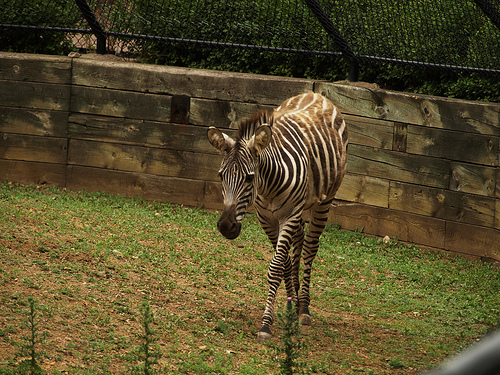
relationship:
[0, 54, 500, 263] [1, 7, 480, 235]
wall on side of a building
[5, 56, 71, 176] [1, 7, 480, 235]
wall on side of a building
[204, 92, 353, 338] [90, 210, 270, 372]
zebra standing in grass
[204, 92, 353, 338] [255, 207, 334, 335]
zebra has legs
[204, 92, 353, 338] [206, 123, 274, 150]
zebra has ears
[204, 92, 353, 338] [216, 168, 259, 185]
zebra has eyes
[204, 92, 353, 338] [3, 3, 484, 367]
zebra standing in an enclosure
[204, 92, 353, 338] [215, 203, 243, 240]
zebra has a snout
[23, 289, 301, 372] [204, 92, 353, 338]
trees in front of zebra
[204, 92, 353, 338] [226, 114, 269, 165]
zebra has a mane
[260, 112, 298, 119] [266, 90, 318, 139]
hairs on back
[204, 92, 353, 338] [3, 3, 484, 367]
zebra inside of enclosure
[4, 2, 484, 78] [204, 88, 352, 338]
fence covering zebra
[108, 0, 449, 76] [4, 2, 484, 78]
trees/bushes on other side of fence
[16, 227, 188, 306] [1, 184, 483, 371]
patches in field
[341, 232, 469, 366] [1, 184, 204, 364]
bottom of a hill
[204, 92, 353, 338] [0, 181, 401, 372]
zebra walking up hill